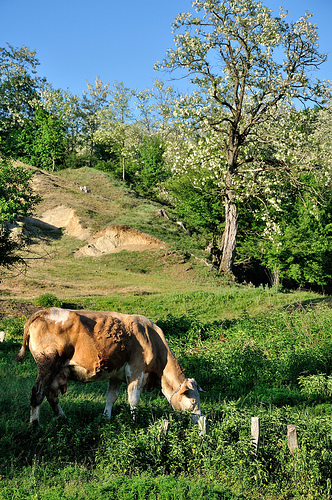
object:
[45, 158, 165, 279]
hill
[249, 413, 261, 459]
post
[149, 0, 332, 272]
tree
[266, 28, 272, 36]
buds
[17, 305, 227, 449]
cow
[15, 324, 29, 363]
tail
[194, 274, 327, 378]
field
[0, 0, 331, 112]
sky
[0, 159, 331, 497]
ground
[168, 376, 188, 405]
rope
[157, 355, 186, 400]
cow's neck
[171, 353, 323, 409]
shadow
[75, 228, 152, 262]
sand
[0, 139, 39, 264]
trees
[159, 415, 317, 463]
fence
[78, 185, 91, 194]
rock